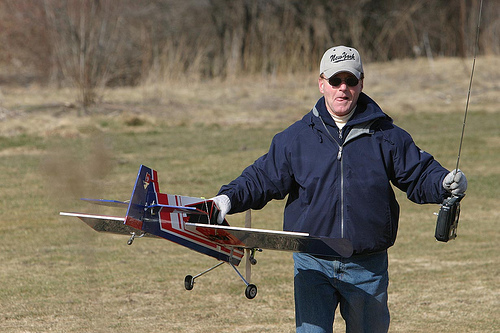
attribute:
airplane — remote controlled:
[58, 166, 355, 298]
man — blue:
[207, 46, 468, 332]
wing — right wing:
[189, 221, 356, 263]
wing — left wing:
[60, 210, 158, 239]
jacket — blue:
[218, 91, 453, 262]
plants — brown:
[137, 34, 224, 90]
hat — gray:
[318, 45, 364, 84]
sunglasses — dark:
[321, 72, 363, 87]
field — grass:
[0, 56, 497, 331]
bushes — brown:
[1, 2, 498, 88]